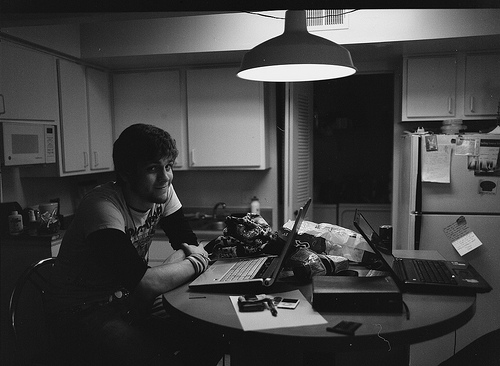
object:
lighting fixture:
[235, 7, 360, 82]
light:
[234, 8, 360, 83]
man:
[51, 118, 210, 365]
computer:
[189, 192, 314, 298]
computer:
[354, 205, 496, 295]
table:
[161, 234, 480, 340]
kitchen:
[2, 3, 497, 365]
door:
[284, 78, 318, 227]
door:
[314, 68, 397, 250]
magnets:
[418, 132, 450, 184]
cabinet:
[400, 53, 500, 121]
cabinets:
[185, 69, 269, 170]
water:
[213, 205, 234, 232]